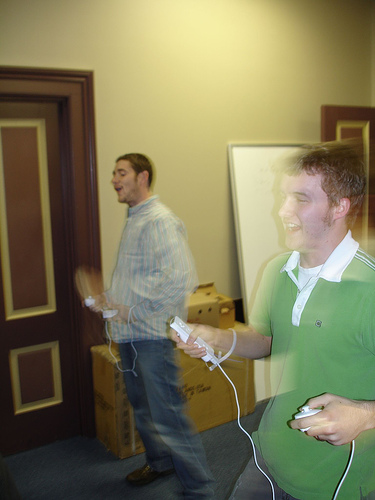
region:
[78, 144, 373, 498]
Two men playing video games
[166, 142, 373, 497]
Man holding a Wii controller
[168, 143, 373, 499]
Man wearing a green shirt and white collar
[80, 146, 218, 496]
Man wearing a white striped shirt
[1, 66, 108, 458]
Dark wood door with wood frame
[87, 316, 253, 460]
Sealed cardboard shipping box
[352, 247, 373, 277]
White stripes on a shirt shoulder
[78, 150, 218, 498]
Man wearing blue jeans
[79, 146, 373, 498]
Two men using Wii controllers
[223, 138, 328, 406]
White panel leaning on a wall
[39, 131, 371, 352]
Men holding game controllers.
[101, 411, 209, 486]
Man with dark brown shoes.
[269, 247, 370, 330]
White collar on the shirt.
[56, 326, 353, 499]
Box on the floor.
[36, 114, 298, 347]
Man in a striped shirt.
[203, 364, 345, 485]
Cord on the remote.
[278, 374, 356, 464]
Hand holding a gaming remote.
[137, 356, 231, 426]
Words on the box.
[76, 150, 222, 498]
man holds wii controller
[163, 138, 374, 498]
man holds wii controller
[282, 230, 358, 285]
collar is turned down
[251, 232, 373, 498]
shirt is worn by man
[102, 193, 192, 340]
buttondown shirt is worn by man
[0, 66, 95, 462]
door is closed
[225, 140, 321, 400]
whiteboard is clean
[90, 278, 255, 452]
boxes are stacked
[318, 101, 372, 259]
door is in background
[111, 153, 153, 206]
man has short haircut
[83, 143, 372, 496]
two young men playing a video game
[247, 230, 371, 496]
green and white shirt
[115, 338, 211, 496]
blue jeans worn by young man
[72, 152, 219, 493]
young man wearing blue jeans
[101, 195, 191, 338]
light colored shirt man is wearing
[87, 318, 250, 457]
cardboard box on the side of the man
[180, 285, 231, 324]
small cardboard box sitting on larger cardboard box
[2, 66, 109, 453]
brown and white door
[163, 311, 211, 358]
white video controller in the young boy's hand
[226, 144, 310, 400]
white board leaning against the wall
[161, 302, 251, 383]
Wii controller with wrist strap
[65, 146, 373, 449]
Two men playing Wii game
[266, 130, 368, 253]
Young man smiling.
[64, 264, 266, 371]
Two Wii controllers being used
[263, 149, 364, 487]
Young man in green polo shirt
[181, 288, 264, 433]
Boxes sitting next to the wall.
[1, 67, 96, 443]
Dark colored interior door with accents.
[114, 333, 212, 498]
Blue denim jeans worn by young man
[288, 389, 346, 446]
Wii joystick controller in left hand.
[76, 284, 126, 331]
Wii joystick controller in right hand.